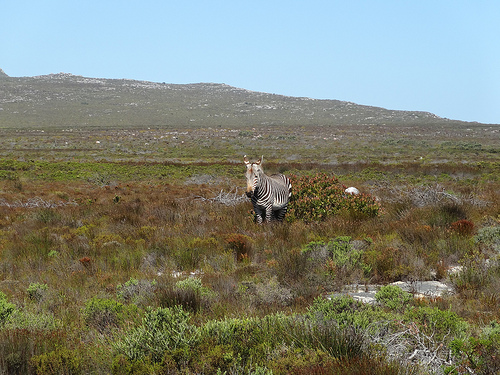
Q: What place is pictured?
A: It is a field.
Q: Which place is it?
A: It is a field.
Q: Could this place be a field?
A: Yes, it is a field.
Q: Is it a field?
A: Yes, it is a field.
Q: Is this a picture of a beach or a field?
A: It is showing a field.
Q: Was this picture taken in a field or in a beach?
A: It was taken at a field.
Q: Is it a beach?
A: No, it is a field.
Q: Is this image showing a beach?
A: No, the picture is showing a field.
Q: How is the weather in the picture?
A: It is clear.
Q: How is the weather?
A: It is clear.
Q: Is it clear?
A: Yes, it is clear.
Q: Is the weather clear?
A: Yes, it is clear.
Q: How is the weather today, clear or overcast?
A: It is clear.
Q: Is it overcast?
A: No, it is clear.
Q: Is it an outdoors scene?
A: Yes, it is outdoors.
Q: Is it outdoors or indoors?
A: It is outdoors.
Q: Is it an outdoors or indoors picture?
A: It is outdoors.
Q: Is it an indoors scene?
A: No, it is outdoors.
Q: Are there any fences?
A: No, there are no fences.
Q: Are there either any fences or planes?
A: No, there are no fences or planes.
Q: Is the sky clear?
A: Yes, the sky is clear.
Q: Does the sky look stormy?
A: No, the sky is clear.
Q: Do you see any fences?
A: No, there are no fences.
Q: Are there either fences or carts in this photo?
A: No, there are no fences or carts.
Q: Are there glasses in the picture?
A: No, there are no glasses.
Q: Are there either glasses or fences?
A: No, there are no glasses or fences.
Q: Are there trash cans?
A: No, there are no trash cans.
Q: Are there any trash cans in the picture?
A: No, there are no trash cans.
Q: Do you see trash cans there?
A: No, there are no trash cans.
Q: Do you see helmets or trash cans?
A: No, there are no trash cans or helmets.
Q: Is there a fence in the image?
A: No, there are no fences.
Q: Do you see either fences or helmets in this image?
A: No, there are no fences or helmets.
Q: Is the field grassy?
A: Yes, the field is grassy.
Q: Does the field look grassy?
A: Yes, the field is grassy.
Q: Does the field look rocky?
A: No, the field is grassy.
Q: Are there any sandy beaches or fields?
A: No, there is a field but it is grassy.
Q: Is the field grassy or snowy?
A: The field is grassy.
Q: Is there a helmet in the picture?
A: No, there are no helmets.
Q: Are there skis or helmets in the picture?
A: No, there are no helmets or skis.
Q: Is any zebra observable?
A: Yes, there is a zebra.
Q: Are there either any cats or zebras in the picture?
A: Yes, there is a zebra.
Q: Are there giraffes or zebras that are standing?
A: Yes, the zebra is standing.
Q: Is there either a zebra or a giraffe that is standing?
A: Yes, the zebra is standing.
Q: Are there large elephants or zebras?
A: Yes, there is a large zebra.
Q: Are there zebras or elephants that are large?
A: Yes, the zebra is large.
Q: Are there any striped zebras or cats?
A: Yes, there is a striped zebra.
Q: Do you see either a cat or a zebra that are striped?
A: Yes, the zebra is striped.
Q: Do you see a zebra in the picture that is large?
A: Yes, there is a large zebra.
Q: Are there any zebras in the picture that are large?
A: Yes, there is a zebra that is large.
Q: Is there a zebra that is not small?
A: Yes, there is a large zebra.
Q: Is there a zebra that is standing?
A: Yes, there is a zebra that is standing.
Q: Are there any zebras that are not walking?
A: Yes, there is a zebra that is standing.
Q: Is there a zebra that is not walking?
A: Yes, there is a zebra that is standing.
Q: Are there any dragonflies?
A: No, there are no dragonflies.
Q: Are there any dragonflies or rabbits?
A: No, there are no dragonflies or rabbits.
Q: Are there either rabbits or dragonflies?
A: No, there are no dragonflies or rabbits.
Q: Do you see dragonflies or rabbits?
A: No, there are no dragonflies or rabbits.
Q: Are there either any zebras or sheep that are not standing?
A: No, there is a zebra but it is standing.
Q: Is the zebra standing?
A: Yes, the zebra is standing.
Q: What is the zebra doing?
A: The zebra is standing.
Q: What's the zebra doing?
A: The zebra is standing.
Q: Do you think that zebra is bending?
A: No, the zebra is standing.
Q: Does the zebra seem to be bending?
A: No, the zebra is standing.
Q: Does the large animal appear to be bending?
A: No, the zebra is standing.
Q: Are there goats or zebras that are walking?
A: No, there is a zebra but it is standing.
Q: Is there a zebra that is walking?
A: No, there is a zebra but it is standing.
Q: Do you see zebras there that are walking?
A: No, there is a zebra but it is standing.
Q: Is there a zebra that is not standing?
A: No, there is a zebra but it is standing.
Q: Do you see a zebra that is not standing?
A: No, there is a zebra but it is standing.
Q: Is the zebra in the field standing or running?
A: The zebra is standing.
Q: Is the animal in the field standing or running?
A: The zebra is standing.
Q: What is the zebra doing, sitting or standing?
A: The zebra is standing.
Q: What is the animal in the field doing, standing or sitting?
A: The zebra is standing.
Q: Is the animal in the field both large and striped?
A: Yes, the zebra is large and striped.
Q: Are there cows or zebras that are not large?
A: No, there is a zebra but it is large.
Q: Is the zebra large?
A: Yes, the zebra is large.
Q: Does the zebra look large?
A: Yes, the zebra is large.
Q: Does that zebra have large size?
A: Yes, the zebra is large.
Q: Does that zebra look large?
A: Yes, the zebra is large.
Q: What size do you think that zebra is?
A: The zebra is large.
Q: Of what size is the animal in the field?
A: The zebra is large.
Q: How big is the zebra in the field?
A: The zebra is large.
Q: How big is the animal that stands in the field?
A: The zebra is large.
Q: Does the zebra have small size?
A: No, the zebra is large.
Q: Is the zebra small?
A: No, the zebra is large.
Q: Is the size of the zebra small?
A: No, the zebra is large.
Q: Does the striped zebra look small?
A: No, the zebra is large.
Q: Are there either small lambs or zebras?
A: No, there is a zebra but it is large.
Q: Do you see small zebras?
A: No, there is a zebra but it is large.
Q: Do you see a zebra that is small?
A: No, there is a zebra but it is large.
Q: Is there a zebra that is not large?
A: No, there is a zebra but it is large.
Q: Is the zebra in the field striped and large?
A: Yes, the zebra is striped and large.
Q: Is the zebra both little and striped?
A: No, the zebra is striped but large.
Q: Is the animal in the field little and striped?
A: No, the zebra is striped but large.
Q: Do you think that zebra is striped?
A: Yes, the zebra is striped.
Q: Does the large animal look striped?
A: Yes, the zebra is striped.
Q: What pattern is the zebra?
A: The zebra is striped.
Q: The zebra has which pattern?
A: The zebra is striped.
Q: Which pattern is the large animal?
A: The zebra is striped.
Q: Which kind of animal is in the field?
A: The animal is a zebra.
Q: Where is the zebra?
A: The zebra is in the field.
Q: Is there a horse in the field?
A: No, there is a zebra in the field.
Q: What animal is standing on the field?
A: The animal is a zebra.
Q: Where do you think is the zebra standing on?
A: The zebra is standing on the field.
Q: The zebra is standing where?
A: The zebra is standing on the field.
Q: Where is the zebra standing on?
A: The zebra is standing on the field.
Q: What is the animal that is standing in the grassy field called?
A: The animal is a zebra.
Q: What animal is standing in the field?
A: The animal is a zebra.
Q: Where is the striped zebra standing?
A: The zebra is standing in the field.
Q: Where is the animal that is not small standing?
A: The zebra is standing in the field.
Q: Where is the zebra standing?
A: The zebra is standing in the field.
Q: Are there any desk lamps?
A: No, there are no desk lamps.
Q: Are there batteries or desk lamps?
A: No, there are no desk lamps or batteries.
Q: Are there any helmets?
A: No, there are no helmets.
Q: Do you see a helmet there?
A: No, there are no helmets.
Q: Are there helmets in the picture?
A: No, there are no helmets.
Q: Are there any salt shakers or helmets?
A: No, there are no helmets or salt shakers.